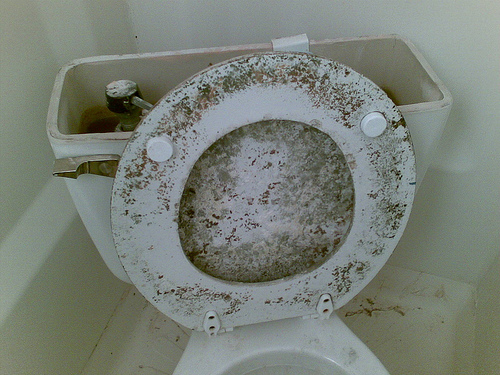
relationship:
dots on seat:
[323, 181, 399, 311] [104, 65, 403, 371]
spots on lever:
[29, 134, 136, 190] [51, 138, 153, 205]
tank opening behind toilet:
[61, 30, 420, 127] [169, 87, 392, 372]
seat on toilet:
[106, 56, 410, 339] [183, 320, 379, 373]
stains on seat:
[172, 91, 214, 110] [124, 59, 388, 307]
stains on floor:
[350, 299, 400, 316] [391, 331, 423, 358]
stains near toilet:
[350, 299, 400, 316] [70, 22, 400, 372]